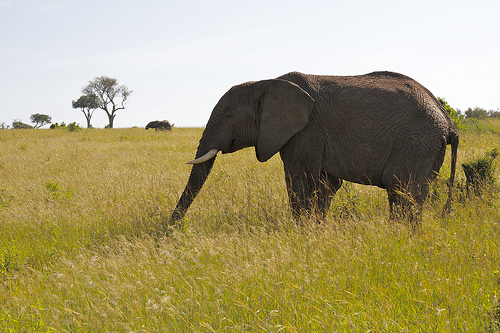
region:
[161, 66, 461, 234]
A large elephant in a big field.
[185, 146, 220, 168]
A white tusk on an elephant.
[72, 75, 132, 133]
Two trees growing side by side.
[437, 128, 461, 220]
An elephant's tail.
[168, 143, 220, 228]
An elephant's trunk.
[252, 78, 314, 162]
A large ear on an elephant.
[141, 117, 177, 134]
An animal in the distance.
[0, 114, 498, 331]
Tall grass.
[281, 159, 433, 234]
An elephant's legs obscured by grass.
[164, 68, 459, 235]
Tough skin on an elephant.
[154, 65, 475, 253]
elephant standing in the grass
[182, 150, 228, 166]
white tusk on the side of the trunk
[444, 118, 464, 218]
gray tail hanging off the bum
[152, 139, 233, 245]
trunk hanging down to the ground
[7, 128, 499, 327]
green grass on the ground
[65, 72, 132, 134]
two trees that are right next to each other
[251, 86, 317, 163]
large gray ear on the side of the head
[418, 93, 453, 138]
light shining on the elephant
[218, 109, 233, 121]
small eye on the side of the head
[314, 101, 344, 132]
lines on the skin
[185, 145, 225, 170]
tusk on an elephant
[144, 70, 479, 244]
grey elephant in a field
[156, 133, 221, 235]
trunk of an elephant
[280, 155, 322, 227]
leg of an elephant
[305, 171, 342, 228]
leg of an elephant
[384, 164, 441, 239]
leg of an elephant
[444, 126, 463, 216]
tail of an elephant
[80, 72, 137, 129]
tree in a field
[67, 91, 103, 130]
tree in a field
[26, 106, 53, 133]
tree in a field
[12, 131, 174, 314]
tall green grass in a field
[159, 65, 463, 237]
gray elephant standing in tall grass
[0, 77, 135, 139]
tall trees and bushes on the horizon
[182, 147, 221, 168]
ivory tusk of an elephant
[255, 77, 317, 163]
large left gray ear of an elephant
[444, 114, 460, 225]
long gray tail of an elephant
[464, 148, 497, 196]
green bush in tall grass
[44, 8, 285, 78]
light blue sky over grassy field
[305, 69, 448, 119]
gray wrinkly skin on the back of an elephant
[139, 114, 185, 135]
dark animals in tall grass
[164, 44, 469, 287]
Elephant in a field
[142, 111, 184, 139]
Animals in a field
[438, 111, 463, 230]
Dark brown tail of an elephant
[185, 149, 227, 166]
White ivory tusk of an elephant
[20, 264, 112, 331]
Patch of green grass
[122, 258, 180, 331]
Patch of green grass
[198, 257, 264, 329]
Patch of green grass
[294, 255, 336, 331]
Patch of green grass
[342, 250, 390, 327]
Patch of green grass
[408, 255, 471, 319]
Patch of green grass